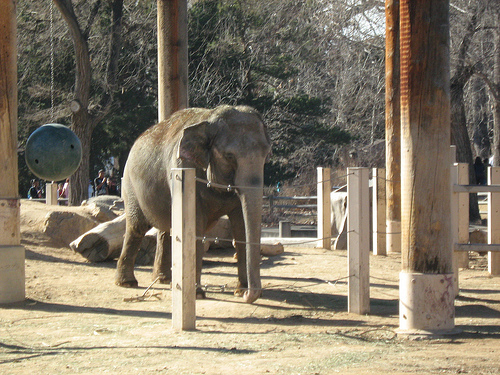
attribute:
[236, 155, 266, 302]
trunk — elephant's, long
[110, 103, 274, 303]
elephant — flappy, gray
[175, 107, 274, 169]
ears — big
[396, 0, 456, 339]
pole — rusty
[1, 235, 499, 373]
sand — brown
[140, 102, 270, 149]
patch — brown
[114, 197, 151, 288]
leg — gray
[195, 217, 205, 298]
leg — gray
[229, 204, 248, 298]
leg — gray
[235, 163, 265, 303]
trunk — gray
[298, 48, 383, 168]
tree — leafless